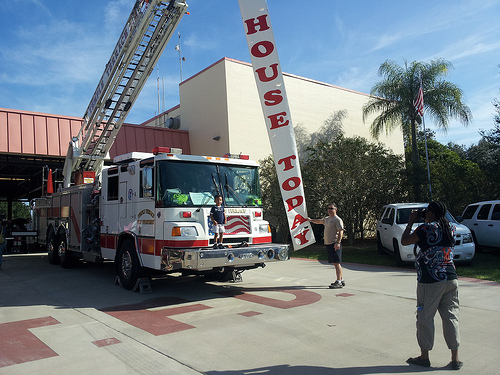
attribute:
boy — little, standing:
[210, 192, 227, 246]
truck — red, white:
[37, 153, 278, 286]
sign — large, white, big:
[243, 5, 315, 251]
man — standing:
[320, 197, 349, 288]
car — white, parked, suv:
[378, 199, 471, 261]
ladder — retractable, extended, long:
[62, 0, 191, 173]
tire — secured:
[114, 234, 145, 287]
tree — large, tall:
[365, 61, 468, 201]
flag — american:
[414, 79, 428, 115]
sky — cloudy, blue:
[7, 0, 500, 124]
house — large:
[7, 59, 411, 249]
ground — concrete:
[17, 257, 487, 371]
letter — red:
[243, 12, 269, 35]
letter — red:
[253, 37, 271, 60]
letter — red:
[259, 62, 277, 85]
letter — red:
[263, 87, 283, 109]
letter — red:
[268, 109, 288, 130]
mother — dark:
[414, 203, 464, 363]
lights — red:
[223, 151, 249, 162]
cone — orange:
[44, 167, 58, 193]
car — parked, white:
[465, 197, 499, 252]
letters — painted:
[1, 284, 320, 361]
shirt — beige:
[321, 211, 347, 244]